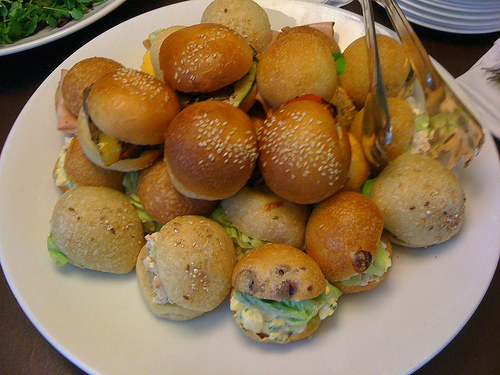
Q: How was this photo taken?
A: By camera.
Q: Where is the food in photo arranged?
A: On plate.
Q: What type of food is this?
A: Mini sandwiches.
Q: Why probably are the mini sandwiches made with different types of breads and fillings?
A: For variety.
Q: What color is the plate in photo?
A: White.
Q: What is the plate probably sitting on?
A: Table.